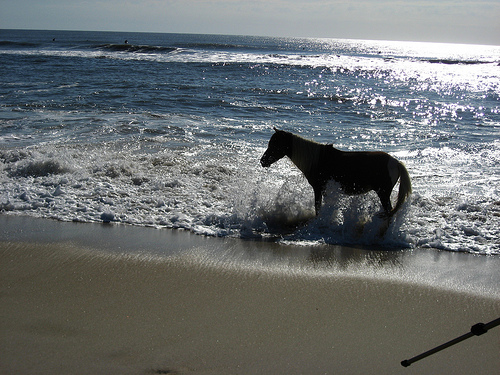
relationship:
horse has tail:
[260, 123, 413, 240] [391, 161, 413, 223]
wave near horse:
[271, 174, 409, 249] [260, 123, 413, 240]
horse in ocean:
[260, 123, 413, 240] [3, 27, 500, 261]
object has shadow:
[461, 206, 499, 285] [402, 318, 498, 368]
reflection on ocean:
[308, 34, 489, 62] [3, 27, 500, 261]